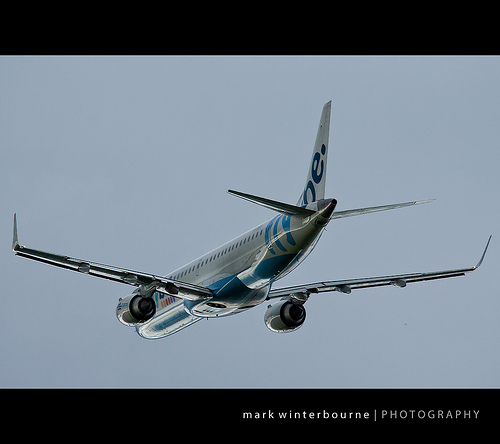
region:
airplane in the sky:
[5, 83, 491, 346]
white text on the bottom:
[238, 407, 485, 424]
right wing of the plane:
[249, 230, 495, 338]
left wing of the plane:
[7, 205, 204, 302]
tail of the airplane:
[227, 103, 423, 232]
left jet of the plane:
[116, 288, 166, 323]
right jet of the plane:
[249, 291, 307, 331]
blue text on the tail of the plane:
[293, 141, 329, 220]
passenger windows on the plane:
[163, 221, 270, 277]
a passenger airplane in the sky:
[5, 96, 487, 342]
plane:
[13, 103, 497, 348]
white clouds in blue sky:
[356, 363, 381, 376]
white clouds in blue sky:
[377, 334, 409, 367]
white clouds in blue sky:
[430, 355, 467, 382]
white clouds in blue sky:
[325, 336, 351, 359]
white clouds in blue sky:
[184, 350, 223, 375]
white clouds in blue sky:
[396, 123, 428, 153]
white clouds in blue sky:
[176, 99, 213, 132]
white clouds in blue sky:
[67, 135, 105, 185]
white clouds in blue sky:
[147, 105, 189, 136]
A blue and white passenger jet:
[9, 99, 493, 341]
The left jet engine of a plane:
[114, 290, 158, 327]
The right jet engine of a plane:
[264, 297, 307, 334]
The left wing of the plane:
[10, 210, 215, 302]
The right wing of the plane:
[264, 231, 494, 301]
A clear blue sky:
[0, 54, 498, 390]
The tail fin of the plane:
[296, 99, 333, 207]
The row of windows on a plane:
[168, 229, 265, 283]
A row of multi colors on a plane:
[157, 293, 177, 308]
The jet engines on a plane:
[114, 291, 307, 333]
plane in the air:
[20, 123, 481, 375]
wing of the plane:
[306, 225, 476, 320]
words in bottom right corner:
[225, 391, 490, 431]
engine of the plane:
[105, 275, 165, 330]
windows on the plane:
[156, 227, 258, 288]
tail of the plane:
[237, 135, 390, 248]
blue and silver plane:
[58, 134, 363, 344]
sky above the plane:
[79, 99, 219, 184]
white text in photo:
[231, 389, 377, 433]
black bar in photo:
[161, 15, 343, 95]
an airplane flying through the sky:
[8, 100, 491, 335]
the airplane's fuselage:
[135, 202, 335, 346]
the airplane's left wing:
[10, 212, 214, 302]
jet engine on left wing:
[117, 288, 155, 321]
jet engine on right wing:
[265, 298, 310, 332]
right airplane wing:
[272, 237, 493, 297]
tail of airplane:
[227, 100, 434, 211]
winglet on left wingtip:
[9, 213, 20, 250]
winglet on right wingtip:
[475, 234, 492, 269]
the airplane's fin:
[301, 100, 334, 205]